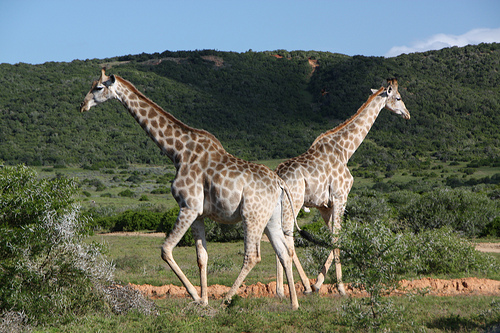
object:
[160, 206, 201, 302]
bent leg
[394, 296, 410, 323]
plant leaves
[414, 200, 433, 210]
plant leaves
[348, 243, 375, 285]
plant leaves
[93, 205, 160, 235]
plant leaves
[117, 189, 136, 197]
plant leaves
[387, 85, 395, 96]
ear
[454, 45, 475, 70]
trees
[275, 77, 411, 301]
giraffe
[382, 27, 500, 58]
clouds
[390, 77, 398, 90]
horns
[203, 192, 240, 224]
stomach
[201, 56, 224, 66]
dirt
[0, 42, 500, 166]
mountain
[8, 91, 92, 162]
hill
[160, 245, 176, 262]
knee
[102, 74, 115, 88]
ear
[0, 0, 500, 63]
sky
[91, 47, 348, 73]
clearing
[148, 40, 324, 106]
hill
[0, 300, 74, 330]
grass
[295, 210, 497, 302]
bush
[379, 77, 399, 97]
hair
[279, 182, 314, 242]
tail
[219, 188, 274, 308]
leg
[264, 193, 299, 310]
leg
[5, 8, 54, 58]
blue skies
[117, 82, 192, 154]
neck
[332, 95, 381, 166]
neck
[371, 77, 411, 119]
head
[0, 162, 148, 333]
brush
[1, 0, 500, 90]
distance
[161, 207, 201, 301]
leg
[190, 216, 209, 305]
leg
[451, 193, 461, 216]
leaves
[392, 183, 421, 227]
plant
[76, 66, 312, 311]
giraffe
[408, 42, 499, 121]
hillside